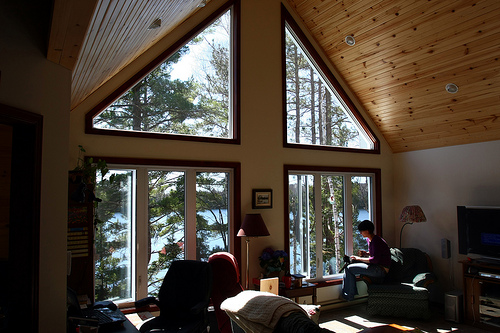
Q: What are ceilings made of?
A: Wood.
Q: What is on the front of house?
A: Windows.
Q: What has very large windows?
A: House.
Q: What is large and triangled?
A: Windows.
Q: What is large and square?
A: Windows.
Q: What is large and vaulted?
A: Ceiling.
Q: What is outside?
A: Trees and nature.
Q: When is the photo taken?
A: Daytime.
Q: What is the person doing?
A: Sitting.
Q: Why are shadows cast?
A: It is sunny.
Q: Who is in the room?
A: A man.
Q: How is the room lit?
A: Through the windows.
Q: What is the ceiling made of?
A: Wood.